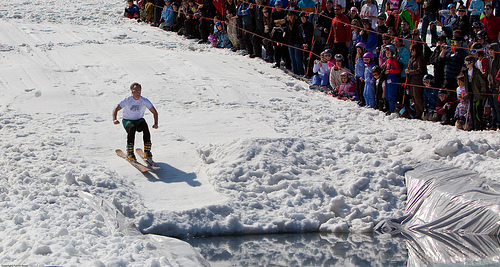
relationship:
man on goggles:
[112, 80, 164, 153] [133, 87, 144, 93]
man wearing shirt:
[112, 80, 164, 153] [117, 94, 152, 123]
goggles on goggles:
[133, 87, 144, 93] [133, 87, 144, 93]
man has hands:
[112, 80, 164, 153] [152, 123, 160, 131]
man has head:
[112, 80, 164, 153] [127, 82, 146, 101]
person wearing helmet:
[365, 51, 375, 111] [362, 50, 373, 61]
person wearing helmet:
[354, 44, 367, 109] [355, 41, 367, 50]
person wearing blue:
[365, 51, 375, 111] [369, 90, 370, 91]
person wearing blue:
[385, 46, 401, 114] [391, 90, 392, 91]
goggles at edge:
[133, 87, 144, 93] [194, 233, 396, 234]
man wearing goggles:
[112, 80, 164, 153] [133, 87, 144, 93]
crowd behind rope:
[128, 1, 497, 124] [325, 16, 329, 18]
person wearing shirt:
[328, 5, 351, 57] [324, 15, 350, 46]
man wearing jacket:
[328, 5, 351, 57] [324, 15, 350, 46]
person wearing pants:
[385, 46, 401, 114] [386, 72, 399, 117]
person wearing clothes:
[410, 44, 424, 120] [413, 57, 421, 118]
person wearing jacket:
[356, 19, 379, 55] [359, 29, 378, 55]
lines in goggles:
[34, 49, 112, 63] [133, 87, 144, 93]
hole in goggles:
[147, 225, 498, 266] [133, 87, 144, 93]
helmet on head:
[362, 50, 373, 61] [361, 52, 376, 67]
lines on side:
[305, 0, 318, 80] [126, 24, 500, 66]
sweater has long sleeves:
[324, 15, 350, 46] [325, 22, 333, 44]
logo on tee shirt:
[129, 104, 141, 111] [117, 94, 152, 123]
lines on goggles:
[123, 143, 157, 150] [133, 87, 144, 93]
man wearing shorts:
[112, 80, 164, 153] [121, 119, 151, 132]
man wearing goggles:
[112, 80, 164, 153] [133, 87, 144, 94]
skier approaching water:
[112, 80, 164, 153] [291, 250, 352, 258]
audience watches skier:
[128, 1, 497, 124] [112, 80, 164, 153]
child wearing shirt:
[385, 46, 401, 114] [385, 56, 403, 79]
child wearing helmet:
[359, 52, 377, 106] [362, 50, 373, 61]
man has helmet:
[385, 46, 401, 114] [384, 44, 396, 54]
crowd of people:
[128, 1, 497, 124] [255, 6, 497, 154]